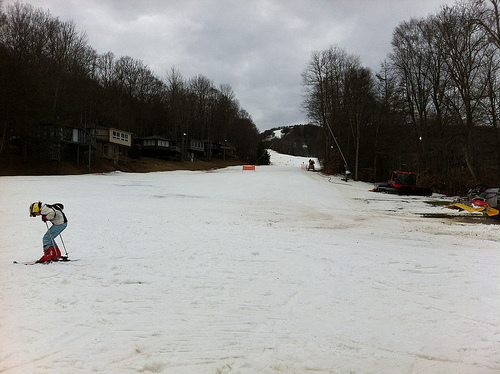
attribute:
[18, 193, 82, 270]
person — below, still, close, here, standing, skiing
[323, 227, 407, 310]
snow — close, here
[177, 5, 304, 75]
sky — above, leafless, close, here, high, overcast, cloudy, grey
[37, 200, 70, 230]
ski jacket — black and white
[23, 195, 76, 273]
person — bending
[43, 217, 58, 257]
pants — green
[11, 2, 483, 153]
sky — cloudy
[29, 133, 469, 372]
snow — white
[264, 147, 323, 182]
hill — tall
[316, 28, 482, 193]
trees — tall